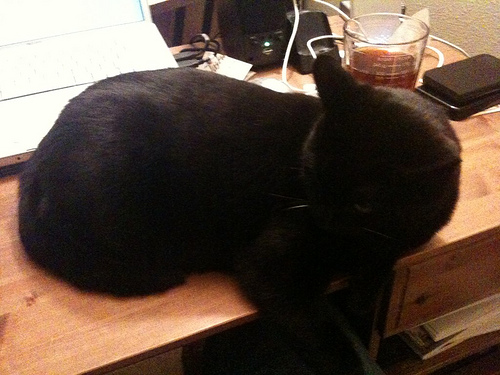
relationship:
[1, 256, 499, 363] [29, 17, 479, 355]
table in photo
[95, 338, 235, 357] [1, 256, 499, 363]
edge of table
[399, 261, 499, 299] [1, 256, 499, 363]
drawer on table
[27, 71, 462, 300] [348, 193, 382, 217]
cat has eye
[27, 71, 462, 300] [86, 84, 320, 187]
cat on back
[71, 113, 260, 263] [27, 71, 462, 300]
body of cat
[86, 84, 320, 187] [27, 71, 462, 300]
back of cat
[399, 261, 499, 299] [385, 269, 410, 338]
drawer has edge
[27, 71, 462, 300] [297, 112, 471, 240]
cat has head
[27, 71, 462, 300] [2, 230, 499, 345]
cat on desk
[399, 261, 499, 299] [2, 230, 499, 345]
drawer of desk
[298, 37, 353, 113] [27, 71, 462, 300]
ear of cat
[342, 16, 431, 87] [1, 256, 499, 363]
glass on table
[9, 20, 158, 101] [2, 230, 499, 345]
laptop on desk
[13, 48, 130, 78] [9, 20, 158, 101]
keyboard on laptop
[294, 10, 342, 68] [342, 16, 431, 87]
wire by glass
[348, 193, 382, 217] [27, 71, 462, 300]
eye on cat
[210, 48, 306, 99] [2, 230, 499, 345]
papers on desk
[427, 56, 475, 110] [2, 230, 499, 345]
hard drives on desk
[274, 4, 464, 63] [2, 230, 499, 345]
cords on desk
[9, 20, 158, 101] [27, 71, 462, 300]
laptop behind cat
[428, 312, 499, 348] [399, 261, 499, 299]
papers in drawer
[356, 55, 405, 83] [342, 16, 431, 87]
liquid in glass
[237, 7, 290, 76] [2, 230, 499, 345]
speaker on desk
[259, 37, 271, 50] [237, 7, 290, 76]
light on speaker